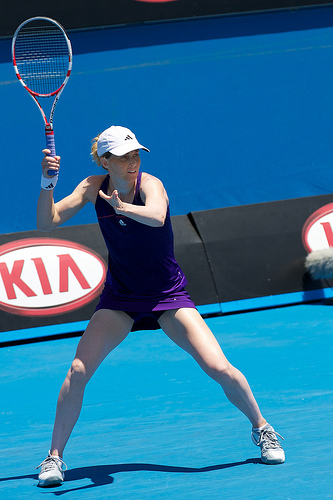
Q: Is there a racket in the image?
A: Yes, there is a racket.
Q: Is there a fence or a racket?
A: Yes, there is a racket.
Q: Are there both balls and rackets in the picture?
A: No, there is a racket but no balls.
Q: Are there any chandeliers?
A: No, there are no chandeliers.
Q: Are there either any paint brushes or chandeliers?
A: No, there are no chandeliers or paint brushes.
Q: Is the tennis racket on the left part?
A: Yes, the tennis racket is on the left of the image.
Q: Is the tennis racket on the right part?
A: No, the tennis racket is on the left of the image.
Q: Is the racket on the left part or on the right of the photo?
A: The racket is on the left of the image.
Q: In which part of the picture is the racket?
A: The racket is on the left of the image.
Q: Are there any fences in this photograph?
A: No, there are no fences.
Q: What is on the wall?
A: The logo is on the wall.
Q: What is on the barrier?
A: The logo is on the barrier.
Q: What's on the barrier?
A: The logo is on the barrier.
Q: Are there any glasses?
A: No, there are no glasses.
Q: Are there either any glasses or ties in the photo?
A: No, there are no glasses or ties.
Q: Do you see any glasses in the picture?
A: No, there are no glasses.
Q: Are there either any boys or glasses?
A: No, there are no glasses or boys.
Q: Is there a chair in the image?
A: No, there are no chairs.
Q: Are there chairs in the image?
A: No, there are no chairs.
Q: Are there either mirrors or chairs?
A: No, there are no chairs or mirrors.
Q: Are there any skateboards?
A: No, there are no skateboards.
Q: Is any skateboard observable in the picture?
A: No, there are no skateboards.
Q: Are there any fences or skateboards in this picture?
A: No, there are no skateboards or fences.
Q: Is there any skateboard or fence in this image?
A: No, there are no skateboards or fences.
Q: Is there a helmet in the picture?
A: No, there are no helmets.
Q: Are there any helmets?
A: No, there are no helmets.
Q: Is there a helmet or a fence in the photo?
A: No, there are no helmets or fences.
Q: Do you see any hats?
A: Yes, there is a hat.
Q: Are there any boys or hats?
A: Yes, there is a hat.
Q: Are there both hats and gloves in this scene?
A: No, there is a hat but no gloves.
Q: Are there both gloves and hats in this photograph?
A: No, there is a hat but no gloves.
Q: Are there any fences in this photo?
A: No, there are no fences.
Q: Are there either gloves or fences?
A: No, there are no fences or gloves.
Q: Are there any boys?
A: No, there are no boys.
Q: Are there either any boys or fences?
A: No, there are no boys or fences.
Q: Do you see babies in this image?
A: No, there are no babies.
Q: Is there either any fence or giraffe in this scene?
A: No, there are no fences or giraffes.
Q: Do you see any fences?
A: No, there are no fences.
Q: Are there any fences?
A: No, there are no fences.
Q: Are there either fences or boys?
A: No, there are no fences or boys.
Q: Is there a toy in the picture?
A: No, there are no toys.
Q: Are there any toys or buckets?
A: No, there are no toys or buckets.